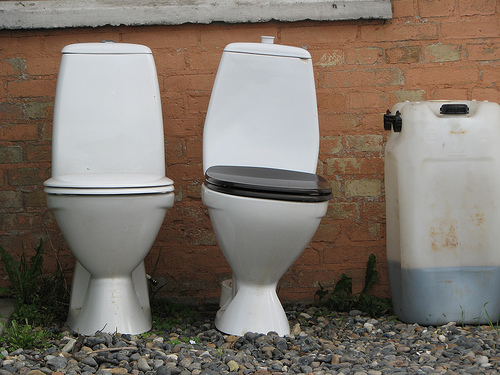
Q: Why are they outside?
A: Because they're broken.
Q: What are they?
A: Toilets.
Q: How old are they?
A: Years.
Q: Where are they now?
A: Outside the building.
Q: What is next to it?
A: A jug.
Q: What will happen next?
A: They will be thrown away.